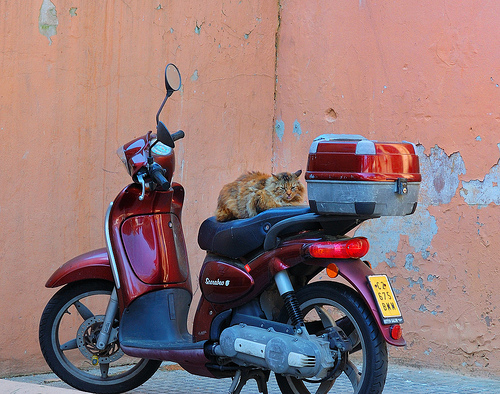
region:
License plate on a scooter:
[363, 268, 415, 326]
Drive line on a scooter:
[211, 313, 338, 387]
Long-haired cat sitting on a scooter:
[210, 163, 305, 221]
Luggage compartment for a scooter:
[300, 116, 427, 227]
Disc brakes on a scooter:
[71, 307, 133, 367]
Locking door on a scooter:
[120, 208, 194, 292]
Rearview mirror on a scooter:
[150, 55, 191, 120]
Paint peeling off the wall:
[437, 112, 490, 199]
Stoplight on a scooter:
[305, 233, 372, 263]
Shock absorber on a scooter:
[265, 264, 317, 339]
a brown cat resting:
[216, 167, 305, 219]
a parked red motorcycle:
[39, 60, 420, 392]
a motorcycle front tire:
[38, 280, 162, 390]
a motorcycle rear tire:
[270, 278, 387, 392]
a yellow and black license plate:
[366, 269, 401, 324]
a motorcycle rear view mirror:
[161, 62, 183, 92]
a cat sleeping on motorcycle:
[35, 61, 423, 392]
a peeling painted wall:
[278, 0, 498, 375]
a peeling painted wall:
[2, 0, 272, 374]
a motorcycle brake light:
[306, 237, 368, 260]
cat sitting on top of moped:
[218, 163, 308, 220]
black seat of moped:
[195, 203, 307, 256]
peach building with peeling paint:
[408, 138, 491, 317]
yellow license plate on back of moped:
[370, 266, 405, 333]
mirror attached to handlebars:
[143, 51, 185, 136]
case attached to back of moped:
[302, 133, 435, 240]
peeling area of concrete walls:
[404, 127, 482, 267]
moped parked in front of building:
[38, 100, 440, 387]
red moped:
[53, 115, 420, 381]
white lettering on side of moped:
[198, 261, 246, 294]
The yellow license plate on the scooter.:
[368, 274, 412, 326]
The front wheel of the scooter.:
[32, 287, 160, 393]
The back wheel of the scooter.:
[269, 287, 391, 391]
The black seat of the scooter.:
[202, 205, 314, 243]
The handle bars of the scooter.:
[141, 100, 191, 180]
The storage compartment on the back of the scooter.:
[305, 125, 430, 202]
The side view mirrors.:
[155, 60, 187, 170]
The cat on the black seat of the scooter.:
[210, 165, 311, 217]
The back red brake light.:
[305, 240, 372, 258]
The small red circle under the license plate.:
[390, 322, 406, 339]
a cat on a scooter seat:
[205, 155, 305, 227]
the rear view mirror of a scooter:
[156, 57, 186, 117]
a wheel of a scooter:
[42, 282, 159, 392]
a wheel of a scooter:
[301, 279, 384, 391]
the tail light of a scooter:
[318, 234, 374, 262]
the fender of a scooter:
[43, 247, 114, 284]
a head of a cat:
[269, 167, 302, 202]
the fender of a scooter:
[358, 257, 408, 348]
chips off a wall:
[431, 147, 496, 215]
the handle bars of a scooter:
[117, 124, 192, 196]